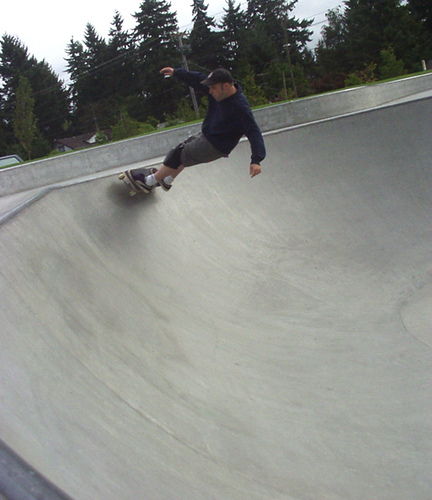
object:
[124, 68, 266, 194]
man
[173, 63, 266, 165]
sweatshirt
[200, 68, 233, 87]
hat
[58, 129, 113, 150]
brown roof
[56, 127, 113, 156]
house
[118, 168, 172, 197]
skateboard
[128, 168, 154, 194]
shoe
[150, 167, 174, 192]
shoe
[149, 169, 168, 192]
sole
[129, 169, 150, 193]
sole